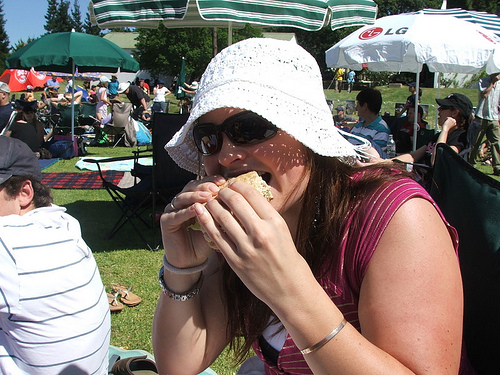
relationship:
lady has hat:
[147, 36, 464, 374] [169, 35, 371, 164]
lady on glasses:
[147, 36, 464, 374] [190, 109, 278, 159]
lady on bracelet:
[147, 36, 464, 374] [300, 316, 347, 356]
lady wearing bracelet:
[147, 36, 464, 374] [295, 318, 348, 356]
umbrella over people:
[323, 8, 495, 79] [353, 91, 388, 152]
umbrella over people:
[323, 8, 495, 79] [398, 92, 429, 149]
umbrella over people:
[323, 8, 495, 79] [426, 91, 475, 167]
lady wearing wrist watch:
[147, 36, 464, 374] [155, 267, 202, 301]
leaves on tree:
[60, 6, 71, 28] [26, 1, 98, 47]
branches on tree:
[38, 1, 60, 23] [26, 1, 98, 47]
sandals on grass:
[107, 276, 144, 309] [39, 142, 242, 373]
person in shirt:
[334, 67, 348, 92] [344, 70, 358, 85]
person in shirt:
[347, 65, 359, 95] [331, 67, 344, 84]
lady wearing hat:
[147, 36, 464, 374] [146, 25, 388, 156]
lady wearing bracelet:
[147, 36, 464, 374] [306, 307, 348, 352]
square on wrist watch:
[173, 291, 180, 303] [155, 267, 206, 302]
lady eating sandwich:
[147, 36, 464, 374] [189, 167, 274, 246]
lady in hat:
[137, 36, 474, 373] [162, 35, 365, 178]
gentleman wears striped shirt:
[0, 136, 109, 373] [0, 204, 109, 373]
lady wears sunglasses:
[147, 36, 464, 374] [178, 94, 305, 159]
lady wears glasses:
[147, 36, 464, 374] [186, 109, 278, 159]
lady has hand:
[147, 36, 464, 374] [191, 176, 303, 297]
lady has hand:
[147, 36, 464, 374] [158, 168, 229, 265]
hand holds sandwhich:
[191, 176, 303, 297] [187, 170, 275, 254]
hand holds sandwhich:
[158, 168, 229, 265] [187, 170, 275, 254]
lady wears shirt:
[147, 36, 464, 374] [185, 168, 467, 368]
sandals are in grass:
[79, 257, 176, 338] [102, 255, 159, 278]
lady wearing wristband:
[147, 36, 464, 374] [152, 242, 206, 303]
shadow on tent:
[67, 190, 129, 245] [78, 0, 382, 40]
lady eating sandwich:
[147, 36, 464, 374] [172, 161, 287, 238]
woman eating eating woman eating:
[131, 36, 465, 373] [170, 169, 290, 244]